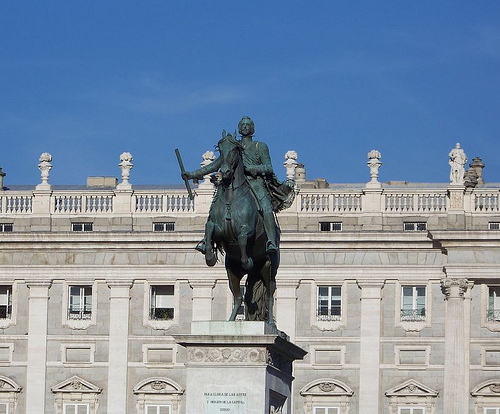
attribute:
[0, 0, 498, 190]
sky — clear, blue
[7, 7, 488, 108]
sky — blue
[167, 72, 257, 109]
cloud — light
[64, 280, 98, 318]
window — open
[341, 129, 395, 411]
column — large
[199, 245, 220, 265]
feet — up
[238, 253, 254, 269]
feet — up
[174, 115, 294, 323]
statue — large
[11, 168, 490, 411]
building — white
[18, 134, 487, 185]
posts — large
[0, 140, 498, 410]
building — white, concrete, tan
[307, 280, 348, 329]
frame — white